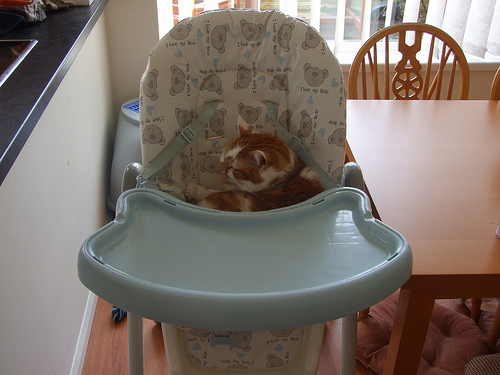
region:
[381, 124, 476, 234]
A smooth table surface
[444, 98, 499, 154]
A smooth table surface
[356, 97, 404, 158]
A smooth table surface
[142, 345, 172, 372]
A smooth floor surface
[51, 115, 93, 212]
A smooth wall surface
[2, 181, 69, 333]
A smooth wall surface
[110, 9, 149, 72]
A smooth wall surface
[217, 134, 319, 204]
A brown and white cat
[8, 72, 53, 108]
A smooth kitchen sink table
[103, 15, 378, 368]
cat in a high chair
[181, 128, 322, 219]
cat resting against cushion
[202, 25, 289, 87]
print on the chair cushion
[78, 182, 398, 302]
blue tray at high chair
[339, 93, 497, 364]
table next to high chair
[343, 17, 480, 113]
chair at the table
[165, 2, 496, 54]
window behind the table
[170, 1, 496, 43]
open blinds at window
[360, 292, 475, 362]
cushion on the floor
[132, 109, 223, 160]
strap on the high chair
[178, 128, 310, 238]
cat is in high chair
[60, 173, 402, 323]
light blue tray on chair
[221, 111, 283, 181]
white and orange ears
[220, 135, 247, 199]
white stripes on cat's face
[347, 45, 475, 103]
wood chair at table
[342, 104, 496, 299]
table is light brown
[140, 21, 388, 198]
white chair with tray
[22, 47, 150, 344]
white wall beside chair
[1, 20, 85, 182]
black counter with sink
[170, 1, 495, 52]
white slats on window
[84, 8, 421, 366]
animal sitting in a high chair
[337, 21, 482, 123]
chair pushed into a table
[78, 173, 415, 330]
tray of the high chair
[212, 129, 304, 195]
head is turned to the side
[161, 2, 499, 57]
blines on the window sill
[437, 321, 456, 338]
indent in the cushion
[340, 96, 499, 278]
table is clear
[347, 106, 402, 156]
light shining on the table